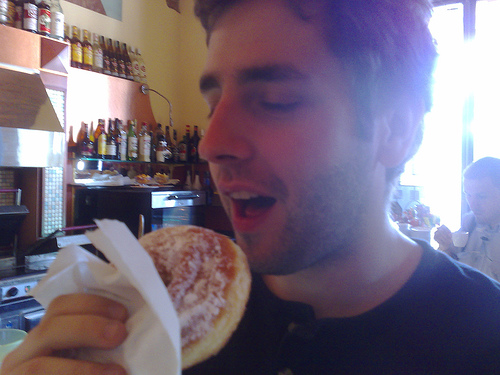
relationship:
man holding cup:
[0, 0, 500, 375] [76, 187, 233, 361]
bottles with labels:
[62, 22, 147, 85] [70, 39, 93, 65]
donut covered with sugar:
[129, 223, 251, 369] [136, 225, 233, 351]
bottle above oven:
[114, 117, 128, 163] [74, 175, 205, 234]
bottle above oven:
[128, 120, 140, 161] [74, 175, 205, 234]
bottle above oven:
[131, 118, 141, 164] [74, 175, 205, 234]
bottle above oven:
[94, 112, 109, 159] [74, 175, 205, 234]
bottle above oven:
[76, 121, 91, 157] [74, 175, 205, 234]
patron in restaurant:
[444, 156, 498, 273] [0, 0, 499, 372]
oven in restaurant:
[3, 209, 53, 316] [0, 0, 499, 372]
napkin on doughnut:
[28, 214, 184, 374] [108, 221, 253, 370]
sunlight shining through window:
[396, 5, 499, 229] [380, 0, 491, 227]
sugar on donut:
[178, 247, 216, 322] [129, 223, 251, 369]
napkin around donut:
[28, 217, 184, 374] [129, 223, 251, 369]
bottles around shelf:
[62, 22, 147, 85] [67, 65, 159, 120]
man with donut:
[2, 3, 498, 373] [129, 223, 251, 369]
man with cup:
[0, 0, 500, 375] [451, 229, 468, 246]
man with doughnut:
[0, 0, 500, 375] [141, 204, 271, 361]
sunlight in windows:
[396, 0, 499, 230] [386, 3, 499, 248]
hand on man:
[2, 287, 134, 372] [2, 3, 498, 373]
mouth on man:
[211, 178, 281, 233] [2, 3, 498, 373]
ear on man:
[374, 79, 426, 162] [2, 3, 498, 373]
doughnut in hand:
[122, 216, 252, 368] [2, 287, 134, 372]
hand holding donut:
[2, 287, 134, 372] [129, 223, 251, 369]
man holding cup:
[447, 151, 497, 291] [447, 228, 471, 251]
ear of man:
[374, 85, 422, 169] [0, 0, 500, 375]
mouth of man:
[218, 179, 281, 233] [2, 3, 498, 373]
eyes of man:
[199, 76, 304, 119] [2, 3, 498, 373]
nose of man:
[196, 109, 256, 164] [184, 16, 461, 226]